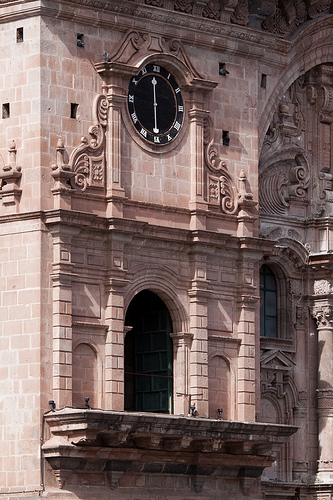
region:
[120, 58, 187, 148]
the clock is black.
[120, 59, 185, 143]
clock's numbers are roman numeral.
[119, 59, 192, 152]
Hands on the clock are white.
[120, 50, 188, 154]
Clock says its 6 o'clock.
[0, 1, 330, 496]
the building is brick.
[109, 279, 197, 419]
The window is arched.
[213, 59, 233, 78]
bird in hole in the wall.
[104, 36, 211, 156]
clock on the building.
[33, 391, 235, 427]
spot lights on the building.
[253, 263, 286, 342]
the window is closed.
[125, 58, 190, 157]
The clock on a building.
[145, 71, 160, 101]
The hand on a clock.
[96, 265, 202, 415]
An archway on a building.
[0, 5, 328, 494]
The building is biege colored.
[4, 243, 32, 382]
The building has bricks on it.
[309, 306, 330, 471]
A column on the building.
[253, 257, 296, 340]
A window on the building.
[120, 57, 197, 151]
Roman numerals on a clock.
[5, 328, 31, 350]
A brick on the side of the building.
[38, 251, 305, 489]
A balcony on the building.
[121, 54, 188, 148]
the numbers are roman numeral.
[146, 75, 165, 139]
hands on the clock are white.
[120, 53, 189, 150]
clock says its 6:00.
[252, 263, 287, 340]
the window is black.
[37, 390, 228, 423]
lights on the building.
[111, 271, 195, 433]
the window is arched.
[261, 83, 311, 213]
carvings on the building.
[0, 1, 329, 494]
the building is brown.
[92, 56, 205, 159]
Black face of the clock.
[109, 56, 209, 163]
Black clock with white numbers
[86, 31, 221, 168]
The clock has Roman numerals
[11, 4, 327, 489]
The building is made of bricks.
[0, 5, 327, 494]
Nobody shown in the photo.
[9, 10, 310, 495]
Photo taken during the day.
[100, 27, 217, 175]
The time is 12:30 pm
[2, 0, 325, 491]
Photo taken in the afternoon.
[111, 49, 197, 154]
The clock hands are white.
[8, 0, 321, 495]
The building is a church.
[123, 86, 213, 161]
Clock has black face.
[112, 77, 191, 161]
Numbers on clock are white.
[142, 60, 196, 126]
Numbers on clock are roman numeral.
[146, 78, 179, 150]
Hands on clock are white.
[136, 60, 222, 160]
Numbers on clock are white.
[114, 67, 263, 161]
Clock is on the side of large building.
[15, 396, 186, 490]
Large concrete bricks on side of building.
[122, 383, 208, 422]
Open doorway on building.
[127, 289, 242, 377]
Large archway near balcony.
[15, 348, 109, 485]
Building is pinkish gray in color.